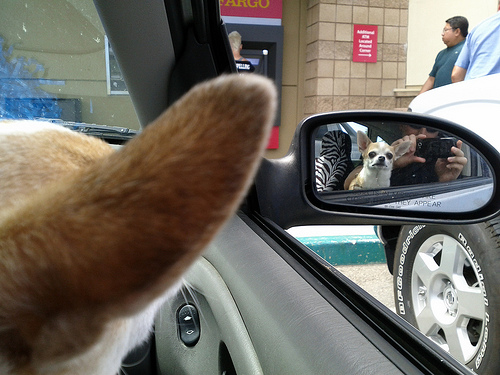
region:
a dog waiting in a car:
[12, 10, 489, 358]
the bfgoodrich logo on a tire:
[380, 220, 444, 317]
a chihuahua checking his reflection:
[337, 128, 416, 192]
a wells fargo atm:
[223, 8, 319, 136]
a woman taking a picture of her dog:
[391, 124, 466, 192]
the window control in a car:
[164, 303, 223, 350]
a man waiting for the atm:
[420, 15, 476, 107]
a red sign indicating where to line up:
[347, 18, 402, 68]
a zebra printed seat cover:
[323, 137, 348, 188]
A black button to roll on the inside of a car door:
[175, 296, 219, 350]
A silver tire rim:
[406, 232, 488, 369]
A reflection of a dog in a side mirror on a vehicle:
[299, 102, 498, 249]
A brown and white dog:
[347, 126, 412, 195]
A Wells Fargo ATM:
[217, 2, 284, 153]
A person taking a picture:
[397, 123, 462, 188]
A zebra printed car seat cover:
[313, 126, 353, 194]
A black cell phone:
[416, 135, 454, 155]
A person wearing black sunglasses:
[400, 123, 442, 146]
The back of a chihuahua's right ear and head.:
[1, 70, 277, 374]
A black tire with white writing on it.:
[392, 215, 499, 374]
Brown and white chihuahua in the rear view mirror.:
[342, 129, 412, 191]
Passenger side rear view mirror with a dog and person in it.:
[298, 107, 498, 225]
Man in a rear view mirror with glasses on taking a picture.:
[392, 119, 467, 185]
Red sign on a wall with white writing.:
[351, 22, 380, 66]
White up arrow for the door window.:
[183, 313, 192, 322]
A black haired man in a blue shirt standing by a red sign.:
[421, 16, 470, 91]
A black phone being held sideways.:
[413, 137, 456, 160]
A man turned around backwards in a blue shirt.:
[452, 4, 499, 81]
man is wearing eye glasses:
[421, 16, 470, 91]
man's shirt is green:
[433, 47, 467, 84]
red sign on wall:
[347, 22, 387, 70]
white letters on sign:
[352, 23, 378, 59]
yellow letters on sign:
[219, 2, 277, 16]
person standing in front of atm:
[216, 0, 286, 157]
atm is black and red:
[218, 14, 290, 154]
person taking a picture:
[307, 114, 472, 190]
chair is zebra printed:
[315, 129, 353, 191]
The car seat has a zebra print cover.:
[311, 121, 356, 191]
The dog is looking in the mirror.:
[335, 126, 415, 191]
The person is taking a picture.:
[395, 115, 472, 182]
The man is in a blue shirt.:
[400, 10, 475, 96]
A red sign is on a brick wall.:
[316, 0, 401, 105]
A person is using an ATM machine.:
[216, 0, 281, 80]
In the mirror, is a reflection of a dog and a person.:
[291, 101, 496, 236]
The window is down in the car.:
[157, 1, 497, 367]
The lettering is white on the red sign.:
[346, 16, 383, 71]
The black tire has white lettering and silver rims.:
[377, 212, 492, 372]